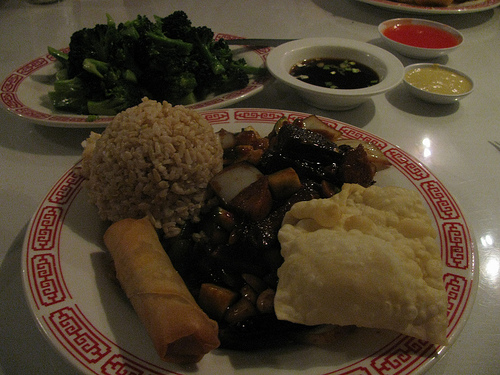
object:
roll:
[98, 213, 220, 364]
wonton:
[272, 182, 455, 348]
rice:
[84, 103, 213, 223]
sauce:
[297, 57, 377, 86]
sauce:
[402, 60, 474, 104]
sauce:
[382, 16, 460, 50]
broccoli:
[156, 74, 198, 106]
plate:
[14, 104, 486, 375]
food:
[97, 140, 404, 329]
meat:
[229, 177, 276, 222]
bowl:
[402, 60, 476, 108]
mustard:
[414, 72, 457, 87]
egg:
[124, 243, 184, 317]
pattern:
[418, 179, 462, 221]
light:
[472, 230, 499, 284]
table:
[6, 7, 494, 364]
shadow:
[267, 89, 375, 130]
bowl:
[266, 37, 406, 111]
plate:
[0, 29, 283, 130]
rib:
[275, 127, 334, 172]